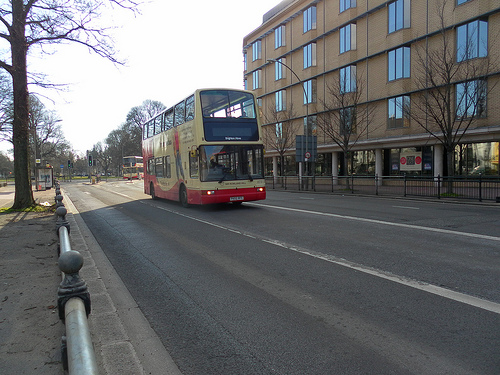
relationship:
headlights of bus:
[199, 180, 268, 201] [131, 77, 270, 217]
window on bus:
[196, 143, 266, 183] [129, 81, 274, 208]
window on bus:
[199, 87, 260, 120] [129, 81, 274, 208]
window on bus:
[184, 96, 198, 118] [129, 81, 274, 208]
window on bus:
[164, 107, 178, 129] [129, 81, 274, 208]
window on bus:
[184, 96, 196, 122] [129, 81, 274, 208]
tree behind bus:
[316, 69, 385, 194] [129, 81, 274, 208]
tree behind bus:
[2, 0, 142, 208] [129, 81, 274, 208]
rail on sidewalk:
[51, 200, 94, 355] [7, 184, 145, 373]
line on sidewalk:
[112, 177, 495, 320] [0, 184, 67, 373]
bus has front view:
[121, 100, 281, 207] [195, 84, 264, 184]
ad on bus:
[166, 129, 196, 184] [131, 77, 270, 217]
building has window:
[242, 0, 499, 186] [386, 45, 408, 80]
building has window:
[242, 0, 499, 186] [455, 20, 489, 62]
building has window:
[242, 0, 499, 186] [338, 64, 355, 94]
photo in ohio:
[137, 85, 270, 207] [4, 7, 494, 372]